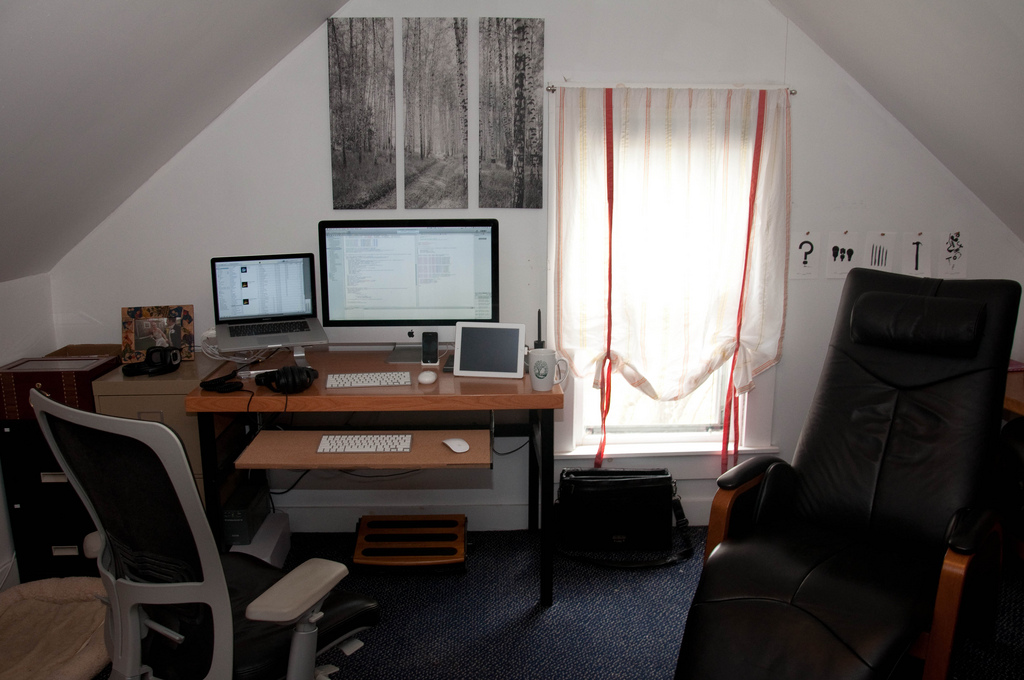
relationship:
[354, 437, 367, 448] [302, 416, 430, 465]
key on computer keyboard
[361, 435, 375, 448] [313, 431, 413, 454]
key on keyboard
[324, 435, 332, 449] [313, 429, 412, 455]
key on keyboard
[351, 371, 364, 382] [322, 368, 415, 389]
key on keyboard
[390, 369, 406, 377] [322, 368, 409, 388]
key on keyboard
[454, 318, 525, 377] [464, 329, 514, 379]
tablet has screen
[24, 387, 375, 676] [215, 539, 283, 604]
office chair has cushion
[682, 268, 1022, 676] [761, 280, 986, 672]
chair has cushions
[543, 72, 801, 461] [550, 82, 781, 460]
curtain on window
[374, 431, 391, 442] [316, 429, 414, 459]
key on a keyboard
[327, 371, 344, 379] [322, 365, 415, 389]
key on a keyboard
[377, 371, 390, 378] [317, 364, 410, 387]
key on a keyboard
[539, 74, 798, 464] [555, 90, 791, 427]
window with curtain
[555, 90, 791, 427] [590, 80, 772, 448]
curtain with drawstring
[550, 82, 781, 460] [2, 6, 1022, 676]
window in room